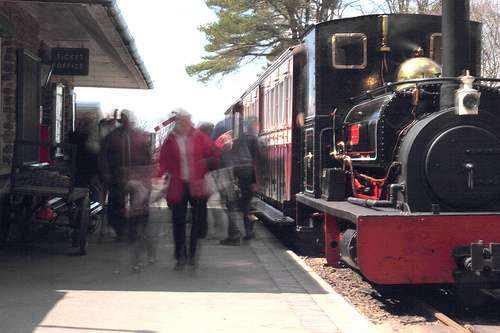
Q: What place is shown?
A: It is a train station.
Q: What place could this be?
A: It is a train station.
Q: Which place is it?
A: It is a train station.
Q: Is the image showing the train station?
A: Yes, it is showing the train station.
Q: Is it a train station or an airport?
A: It is a train station.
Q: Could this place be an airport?
A: No, it is a train station.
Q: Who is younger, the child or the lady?
A: The child is younger than the lady.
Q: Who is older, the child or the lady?
A: The lady is older than the child.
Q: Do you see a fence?
A: No, there are no fences.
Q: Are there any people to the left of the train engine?
A: Yes, there are people to the left of the train engine.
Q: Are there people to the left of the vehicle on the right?
A: Yes, there are people to the left of the train engine.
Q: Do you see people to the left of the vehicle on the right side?
A: Yes, there are people to the left of the train engine.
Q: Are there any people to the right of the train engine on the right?
A: No, the people are to the left of the locomotive.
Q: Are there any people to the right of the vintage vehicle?
A: No, the people are to the left of the locomotive.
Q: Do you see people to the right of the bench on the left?
A: Yes, there are people to the right of the bench.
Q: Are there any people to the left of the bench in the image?
A: No, the people are to the right of the bench.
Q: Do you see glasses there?
A: No, there are no glasses.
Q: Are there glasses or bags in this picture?
A: No, there are no glasses or bags.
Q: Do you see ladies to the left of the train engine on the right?
A: Yes, there is a lady to the left of the train engine.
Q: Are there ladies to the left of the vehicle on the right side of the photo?
A: Yes, there is a lady to the left of the train engine.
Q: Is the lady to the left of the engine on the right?
A: Yes, the lady is to the left of the train engine.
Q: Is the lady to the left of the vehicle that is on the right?
A: Yes, the lady is to the left of the train engine.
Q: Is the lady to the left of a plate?
A: No, the lady is to the left of the train engine.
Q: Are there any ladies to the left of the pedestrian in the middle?
A: Yes, there is a lady to the left of the pedestrian.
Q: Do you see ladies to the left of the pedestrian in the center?
A: Yes, there is a lady to the left of the pedestrian.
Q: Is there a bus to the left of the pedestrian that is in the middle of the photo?
A: No, there is a lady to the left of the pedestrian.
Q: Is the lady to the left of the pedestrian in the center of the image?
A: Yes, the lady is to the left of the pedestrian.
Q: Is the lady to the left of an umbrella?
A: No, the lady is to the left of the pedestrian.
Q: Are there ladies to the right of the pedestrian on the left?
A: Yes, there is a lady to the right of the pedestrian.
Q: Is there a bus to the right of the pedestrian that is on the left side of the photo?
A: No, there is a lady to the right of the pedestrian.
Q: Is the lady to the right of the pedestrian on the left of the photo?
A: Yes, the lady is to the right of the pedestrian.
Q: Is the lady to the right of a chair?
A: No, the lady is to the right of the pedestrian.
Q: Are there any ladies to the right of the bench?
A: Yes, there is a lady to the right of the bench.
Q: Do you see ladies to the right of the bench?
A: Yes, there is a lady to the right of the bench.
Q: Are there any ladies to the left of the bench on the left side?
A: No, the lady is to the right of the bench.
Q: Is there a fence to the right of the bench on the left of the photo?
A: No, there is a lady to the right of the bench.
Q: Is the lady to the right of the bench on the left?
A: Yes, the lady is to the right of the bench.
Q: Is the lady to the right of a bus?
A: No, the lady is to the right of the bench.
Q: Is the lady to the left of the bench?
A: No, the lady is to the right of the bench.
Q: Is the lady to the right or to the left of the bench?
A: The lady is to the right of the bench.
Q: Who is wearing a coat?
A: The lady is wearing a coat.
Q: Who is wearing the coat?
A: The lady is wearing a coat.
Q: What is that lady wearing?
A: The lady is wearing a coat.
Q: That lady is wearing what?
A: The lady is wearing a coat.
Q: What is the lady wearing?
A: The lady is wearing a coat.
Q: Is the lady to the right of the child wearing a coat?
A: Yes, the lady is wearing a coat.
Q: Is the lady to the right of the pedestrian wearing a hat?
A: No, the lady is wearing a coat.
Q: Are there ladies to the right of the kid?
A: Yes, there is a lady to the right of the kid.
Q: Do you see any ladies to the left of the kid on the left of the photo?
A: No, the lady is to the right of the kid.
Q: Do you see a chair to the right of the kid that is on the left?
A: No, there is a lady to the right of the child.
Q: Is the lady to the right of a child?
A: Yes, the lady is to the right of a child.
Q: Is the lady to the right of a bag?
A: No, the lady is to the right of a child.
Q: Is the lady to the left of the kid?
A: No, the lady is to the right of the kid.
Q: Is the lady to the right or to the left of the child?
A: The lady is to the right of the child.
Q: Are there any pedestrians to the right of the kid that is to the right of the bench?
A: Yes, there is a pedestrian to the right of the child.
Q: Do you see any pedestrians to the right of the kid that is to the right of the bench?
A: Yes, there is a pedestrian to the right of the child.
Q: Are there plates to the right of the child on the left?
A: No, there is a pedestrian to the right of the child.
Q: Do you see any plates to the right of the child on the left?
A: No, there is a pedestrian to the right of the child.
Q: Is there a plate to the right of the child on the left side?
A: No, there is a pedestrian to the right of the child.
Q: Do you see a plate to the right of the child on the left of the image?
A: No, there is a pedestrian to the right of the child.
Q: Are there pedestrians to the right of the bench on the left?
A: Yes, there is a pedestrian to the right of the bench.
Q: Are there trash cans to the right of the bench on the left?
A: No, there is a pedestrian to the right of the bench.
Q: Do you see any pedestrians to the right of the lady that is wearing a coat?
A: Yes, there is a pedestrian to the right of the lady.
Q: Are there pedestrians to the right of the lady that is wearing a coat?
A: Yes, there is a pedestrian to the right of the lady.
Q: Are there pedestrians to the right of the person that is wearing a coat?
A: Yes, there is a pedestrian to the right of the lady.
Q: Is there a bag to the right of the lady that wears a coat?
A: No, there is a pedestrian to the right of the lady.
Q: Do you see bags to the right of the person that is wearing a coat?
A: No, there is a pedestrian to the right of the lady.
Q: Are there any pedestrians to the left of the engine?
A: Yes, there is a pedestrian to the left of the engine.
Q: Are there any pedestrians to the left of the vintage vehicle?
A: Yes, there is a pedestrian to the left of the engine.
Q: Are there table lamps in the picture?
A: No, there are no table lamps.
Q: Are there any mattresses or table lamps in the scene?
A: No, there are no table lamps or mattresses.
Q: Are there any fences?
A: No, there are no fences.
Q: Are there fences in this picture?
A: No, there are no fences.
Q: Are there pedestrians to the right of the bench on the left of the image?
A: Yes, there is a pedestrian to the right of the bench.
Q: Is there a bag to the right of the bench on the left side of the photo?
A: No, there is a pedestrian to the right of the bench.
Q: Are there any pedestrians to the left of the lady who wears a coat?
A: Yes, there is a pedestrian to the left of the lady.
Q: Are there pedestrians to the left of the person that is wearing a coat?
A: Yes, there is a pedestrian to the left of the lady.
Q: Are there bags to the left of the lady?
A: No, there is a pedestrian to the left of the lady.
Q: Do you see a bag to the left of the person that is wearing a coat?
A: No, there is a pedestrian to the left of the lady.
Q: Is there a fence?
A: No, there are no fences.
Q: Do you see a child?
A: Yes, there is a child.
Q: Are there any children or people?
A: Yes, there is a child.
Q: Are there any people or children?
A: Yes, there is a child.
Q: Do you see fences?
A: No, there are no fences.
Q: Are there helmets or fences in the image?
A: No, there are no fences or helmets.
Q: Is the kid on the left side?
A: Yes, the kid is on the left of the image.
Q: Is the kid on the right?
A: No, the kid is on the left of the image.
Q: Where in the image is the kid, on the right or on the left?
A: The kid is on the left of the image.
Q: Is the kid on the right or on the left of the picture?
A: The kid is on the left of the image.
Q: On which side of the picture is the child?
A: The child is on the left of the image.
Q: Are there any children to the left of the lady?
A: Yes, there is a child to the left of the lady.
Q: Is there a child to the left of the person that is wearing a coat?
A: Yes, there is a child to the left of the lady.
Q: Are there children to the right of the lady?
A: No, the child is to the left of the lady.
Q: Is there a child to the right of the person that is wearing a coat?
A: No, the child is to the left of the lady.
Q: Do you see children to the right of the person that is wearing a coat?
A: No, the child is to the left of the lady.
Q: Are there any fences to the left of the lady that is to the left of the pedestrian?
A: No, there is a child to the left of the lady.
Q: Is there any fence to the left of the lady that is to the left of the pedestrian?
A: No, there is a child to the left of the lady.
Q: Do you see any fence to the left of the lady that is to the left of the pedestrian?
A: No, there is a child to the left of the lady.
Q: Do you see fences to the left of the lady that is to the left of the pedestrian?
A: No, there is a child to the left of the lady.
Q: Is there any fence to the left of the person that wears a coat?
A: No, there is a child to the left of the lady.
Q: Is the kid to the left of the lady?
A: Yes, the kid is to the left of the lady.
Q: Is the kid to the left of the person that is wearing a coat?
A: Yes, the kid is to the left of the lady.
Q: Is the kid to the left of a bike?
A: No, the kid is to the left of the lady.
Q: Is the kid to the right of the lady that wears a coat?
A: No, the kid is to the left of the lady.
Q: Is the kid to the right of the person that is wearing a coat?
A: No, the kid is to the left of the lady.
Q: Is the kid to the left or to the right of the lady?
A: The kid is to the left of the lady.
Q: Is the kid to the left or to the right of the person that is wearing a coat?
A: The kid is to the left of the lady.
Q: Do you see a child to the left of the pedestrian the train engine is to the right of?
A: Yes, there is a child to the left of the pedestrian.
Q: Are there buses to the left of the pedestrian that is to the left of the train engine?
A: No, there is a child to the left of the pedestrian.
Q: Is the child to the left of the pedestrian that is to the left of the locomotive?
A: Yes, the child is to the left of the pedestrian.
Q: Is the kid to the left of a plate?
A: No, the kid is to the left of the pedestrian.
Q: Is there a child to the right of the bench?
A: Yes, there is a child to the right of the bench.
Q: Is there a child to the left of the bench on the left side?
A: No, the child is to the right of the bench.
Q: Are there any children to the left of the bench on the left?
A: No, the child is to the right of the bench.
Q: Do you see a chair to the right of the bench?
A: No, there is a child to the right of the bench.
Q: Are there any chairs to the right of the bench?
A: No, there is a child to the right of the bench.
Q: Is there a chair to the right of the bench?
A: No, there is a child to the right of the bench.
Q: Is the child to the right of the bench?
A: Yes, the child is to the right of the bench.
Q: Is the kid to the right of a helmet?
A: No, the kid is to the right of the bench.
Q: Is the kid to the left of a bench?
A: No, the kid is to the right of a bench.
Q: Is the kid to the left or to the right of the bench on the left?
A: The kid is to the right of the bench.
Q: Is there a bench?
A: Yes, there is a bench.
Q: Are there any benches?
A: Yes, there is a bench.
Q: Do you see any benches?
A: Yes, there is a bench.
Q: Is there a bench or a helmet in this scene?
A: Yes, there is a bench.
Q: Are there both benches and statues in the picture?
A: No, there is a bench but no statues.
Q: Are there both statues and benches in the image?
A: No, there is a bench but no statues.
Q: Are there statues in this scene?
A: No, there are no statues.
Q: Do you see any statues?
A: No, there are no statues.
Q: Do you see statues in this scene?
A: No, there are no statues.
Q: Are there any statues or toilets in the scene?
A: No, there are no statues or toilets.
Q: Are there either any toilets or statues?
A: No, there are no statues or toilets.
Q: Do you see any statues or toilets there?
A: No, there are no statues or toilets.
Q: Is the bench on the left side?
A: Yes, the bench is on the left of the image.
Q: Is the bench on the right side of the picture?
A: No, the bench is on the left of the image.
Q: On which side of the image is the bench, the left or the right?
A: The bench is on the left of the image.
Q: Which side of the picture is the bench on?
A: The bench is on the left of the image.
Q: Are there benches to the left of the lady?
A: Yes, there is a bench to the left of the lady.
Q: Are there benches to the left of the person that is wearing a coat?
A: Yes, there is a bench to the left of the lady.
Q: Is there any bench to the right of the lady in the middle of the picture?
A: No, the bench is to the left of the lady.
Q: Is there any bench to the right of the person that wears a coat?
A: No, the bench is to the left of the lady.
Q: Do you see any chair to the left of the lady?
A: No, there is a bench to the left of the lady.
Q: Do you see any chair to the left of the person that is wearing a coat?
A: No, there is a bench to the left of the lady.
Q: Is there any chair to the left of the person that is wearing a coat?
A: No, there is a bench to the left of the lady.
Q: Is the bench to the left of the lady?
A: Yes, the bench is to the left of the lady.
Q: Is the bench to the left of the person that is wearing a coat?
A: Yes, the bench is to the left of the lady.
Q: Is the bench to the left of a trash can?
A: No, the bench is to the left of the lady.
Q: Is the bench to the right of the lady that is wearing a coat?
A: No, the bench is to the left of the lady.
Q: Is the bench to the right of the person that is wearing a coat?
A: No, the bench is to the left of the lady.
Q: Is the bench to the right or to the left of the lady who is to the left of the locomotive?
A: The bench is to the left of the lady.